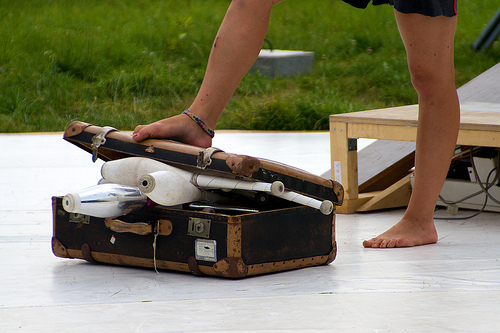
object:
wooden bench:
[327, 100, 500, 214]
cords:
[433, 165, 498, 221]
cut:
[214, 36, 221, 47]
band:
[182, 109, 215, 138]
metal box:
[248, 48, 315, 79]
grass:
[0, 0, 500, 134]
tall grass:
[248, 92, 333, 130]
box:
[49, 119, 345, 279]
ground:
[0, 0, 500, 133]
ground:
[0, 129, 500, 333]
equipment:
[61, 182, 160, 219]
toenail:
[372, 242, 377, 245]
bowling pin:
[100, 156, 285, 196]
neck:
[191, 174, 271, 193]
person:
[131, 0, 461, 249]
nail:
[133, 134, 138, 137]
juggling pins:
[137, 171, 230, 208]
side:
[233, 204, 336, 280]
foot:
[131, 112, 214, 148]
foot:
[362, 217, 438, 249]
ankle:
[181, 103, 221, 137]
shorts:
[342, 0, 459, 17]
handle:
[104, 216, 173, 236]